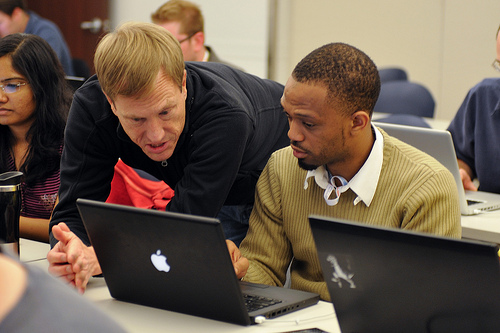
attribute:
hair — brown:
[92, 24, 189, 107]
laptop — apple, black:
[79, 197, 319, 326]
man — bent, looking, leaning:
[223, 43, 463, 304]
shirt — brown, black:
[239, 125, 463, 303]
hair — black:
[294, 44, 380, 119]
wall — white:
[278, 5, 497, 122]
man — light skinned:
[47, 23, 291, 295]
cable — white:
[256, 308, 337, 327]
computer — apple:
[77, 197, 319, 326]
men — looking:
[49, 23, 461, 303]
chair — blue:
[371, 67, 436, 129]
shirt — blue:
[448, 78, 500, 194]